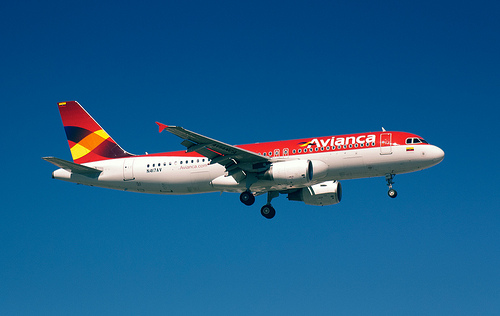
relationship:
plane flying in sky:
[43, 101, 448, 219] [1, 2, 498, 314]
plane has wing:
[43, 101, 448, 219] [154, 119, 271, 184]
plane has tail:
[43, 101, 448, 219] [55, 98, 130, 165]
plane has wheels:
[43, 101, 448, 219] [240, 190, 278, 221]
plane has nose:
[43, 101, 448, 219] [430, 143, 445, 168]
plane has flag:
[43, 101, 448, 219] [406, 146, 417, 154]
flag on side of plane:
[406, 146, 417, 154] [43, 101, 448, 219]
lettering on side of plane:
[311, 136, 376, 145] [43, 101, 448, 219]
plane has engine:
[43, 101, 448, 219] [262, 159, 314, 185]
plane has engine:
[43, 101, 448, 219] [296, 181, 343, 207]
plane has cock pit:
[43, 101, 448, 219] [403, 136, 427, 144]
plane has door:
[43, 101, 448, 219] [380, 132, 392, 157]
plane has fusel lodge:
[43, 101, 448, 219] [212, 160, 341, 208]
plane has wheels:
[43, 101, 448, 219] [381, 172, 398, 201]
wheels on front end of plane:
[381, 172, 398, 201] [43, 101, 448, 219]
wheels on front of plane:
[381, 172, 398, 201] [43, 101, 448, 219]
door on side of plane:
[380, 132, 392, 157] [43, 101, 448, 219]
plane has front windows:
[43, 101, 448, 219] [407, 135, 429, 147]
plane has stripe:
[43, 101, 448, 219] [72, 130, 430, 160]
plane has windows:
[43, 101, 448, 219] [146, 140, 378, 167]